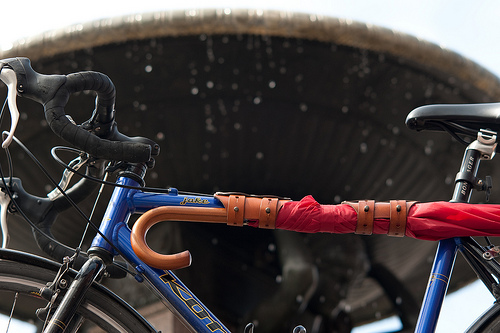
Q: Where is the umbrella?
A: On the bicycle.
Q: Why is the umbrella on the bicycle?
A: In case it rains.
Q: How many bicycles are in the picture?
A: One.